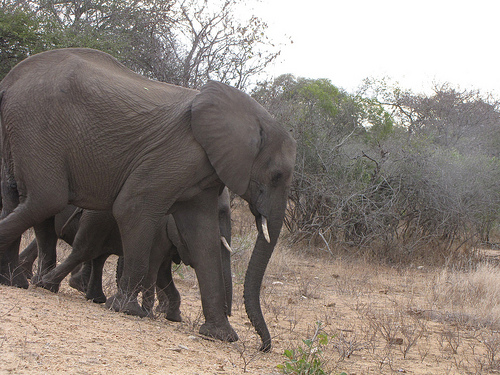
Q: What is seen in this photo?
A: Elephants in the safari.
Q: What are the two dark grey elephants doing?
A: Walking in the woods.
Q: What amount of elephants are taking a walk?
A: Two.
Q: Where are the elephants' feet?
A: On the ground.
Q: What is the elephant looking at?
A: The ground.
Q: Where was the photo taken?
A: Outside somewhere.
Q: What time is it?
A: Afternoon.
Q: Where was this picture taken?
A: In the wild.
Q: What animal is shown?
A: Elephant.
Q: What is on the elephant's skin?
A: Wrinkles.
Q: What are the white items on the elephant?
A: Tusks.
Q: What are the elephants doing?
A: Walking.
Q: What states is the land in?
A: Dry with little grass or leaves.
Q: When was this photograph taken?
A: During the day time.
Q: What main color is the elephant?
A: Grey.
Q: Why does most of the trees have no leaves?
A: It's dry season.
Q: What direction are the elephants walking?
A: Downhill.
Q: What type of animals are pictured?
A: Elephants.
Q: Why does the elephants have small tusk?
A: Young elephants.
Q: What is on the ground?
A: Dirt.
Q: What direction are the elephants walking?
A: Right.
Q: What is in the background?
A: Trees.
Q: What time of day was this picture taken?
A: Afternoon.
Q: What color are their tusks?
A: White.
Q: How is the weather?
A: Clear.